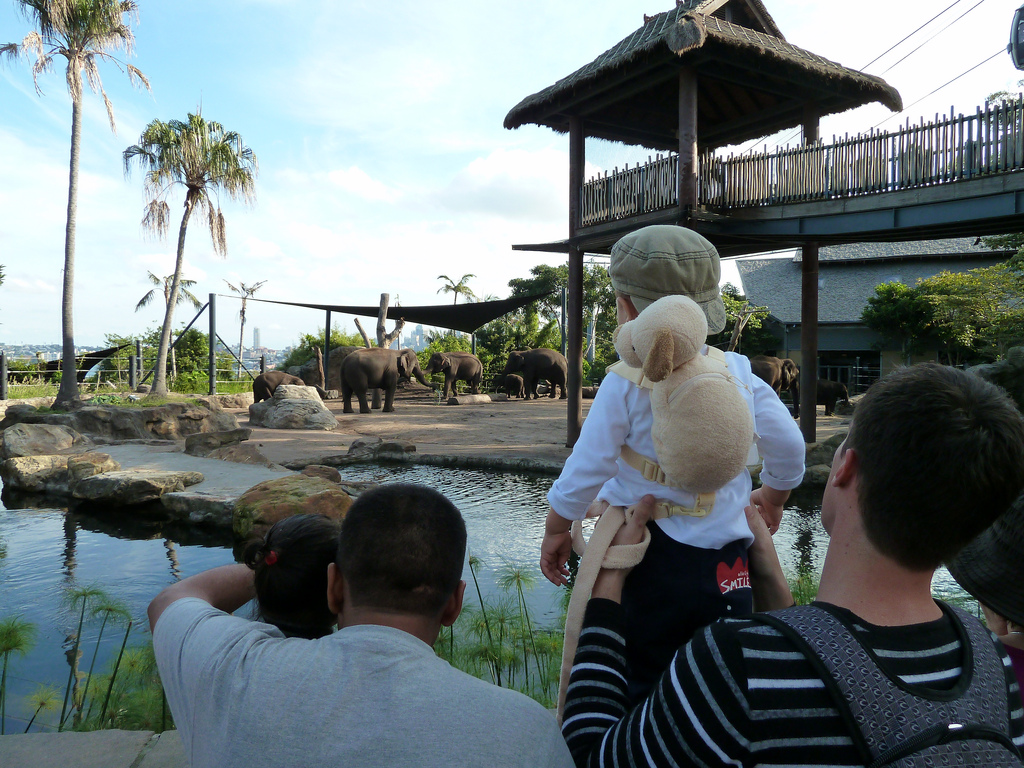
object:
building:
[736, 232, 1024, 406]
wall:
[737, 250, 1024, 322]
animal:
[340, 349, 435, 414]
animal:
[421, 351, 482, 401]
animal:
[254, 370, 308, 403]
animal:
[485, 349, 565, 401]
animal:
[751, 354, 801, 419]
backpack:
[734, 597, 1024, 768]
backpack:
[603, 293, 763, 495]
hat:
[608, 224, 728, 336]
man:
[562, 362, 1024, 766]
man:
[143, 484, 579, 766]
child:
[539, 223, 804, 705]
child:
[232, 513, 341, 640]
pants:
[622, 520, 754, 715]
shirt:
[547, 344, 805, 551]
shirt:
[150, 597, 575, 768]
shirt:
[559, 598, 1024, 768]